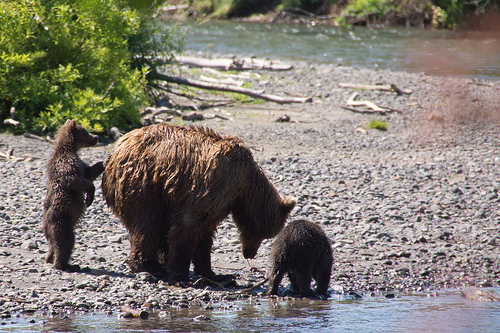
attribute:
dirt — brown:
[176, 56, 498, 282]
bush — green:
[0, 1, 150, 128]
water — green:
[315, 28, 412, 83]